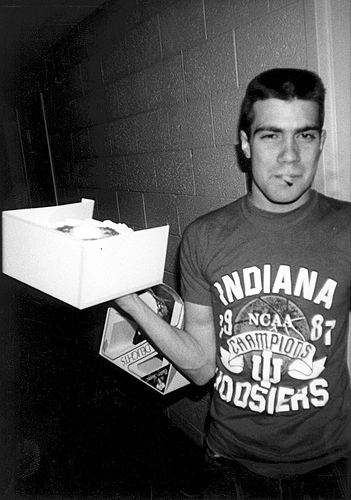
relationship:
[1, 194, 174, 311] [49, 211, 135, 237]
box with cake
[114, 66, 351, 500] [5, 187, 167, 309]
man with box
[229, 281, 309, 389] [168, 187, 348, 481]
basketball on shirt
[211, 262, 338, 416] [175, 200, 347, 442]
fabric on shirt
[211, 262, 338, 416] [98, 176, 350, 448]
fabric on shirt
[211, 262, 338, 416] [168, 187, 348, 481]
fabric on shirt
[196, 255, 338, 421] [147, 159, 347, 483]
fabric on shirt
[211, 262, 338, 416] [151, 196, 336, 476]
fabric on shirt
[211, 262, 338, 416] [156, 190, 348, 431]
fabric on shirt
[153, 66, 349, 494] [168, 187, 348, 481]
man wearing shirt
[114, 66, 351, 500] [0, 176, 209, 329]
man holding box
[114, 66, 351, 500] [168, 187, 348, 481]
man wearing shirt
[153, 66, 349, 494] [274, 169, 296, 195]
man smoking cigarette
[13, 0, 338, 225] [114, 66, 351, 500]
wall behind man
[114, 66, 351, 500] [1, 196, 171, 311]
man holding box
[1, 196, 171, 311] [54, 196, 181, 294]
box has flap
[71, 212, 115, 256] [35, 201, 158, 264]
light on cake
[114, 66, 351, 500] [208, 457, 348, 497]
man has pants